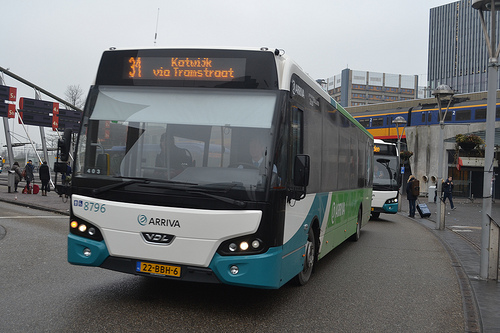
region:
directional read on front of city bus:
[103, 41, 265, 106]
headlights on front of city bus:
[207, 216, 285, 293]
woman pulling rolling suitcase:
[403, 162, 439, 225]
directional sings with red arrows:
[5, 76, 88, 156]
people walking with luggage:
[10, 145, 62, 204]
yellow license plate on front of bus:
[132, 250, 197, 289]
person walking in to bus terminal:
[438, 171, 466, 228]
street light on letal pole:
[433, 66, 466, 186]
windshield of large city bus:
[83, 84, 282, 194]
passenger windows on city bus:
[286, 75, 408, 210]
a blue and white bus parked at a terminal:
[52, 39, 384, 294]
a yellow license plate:
[134, 251, 191, 280]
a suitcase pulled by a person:
[414, 193, 434, 230]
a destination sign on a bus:
[97, 47, 252, 89]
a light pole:
[464, 1, 498, 286]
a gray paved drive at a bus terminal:
[7, 193, 469, 331]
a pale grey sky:
[2, 4, 425, 150]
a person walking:
[438, 171, 458, 209]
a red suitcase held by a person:
[31, 183, 41, 197]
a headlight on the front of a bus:
[236, 238, 250, 255]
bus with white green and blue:
[75, 38, 430, 299]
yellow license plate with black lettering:
[118, 242, 199, 280]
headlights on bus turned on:
[62, 215, 339, 270]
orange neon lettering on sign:
[114, 45, 316, 106]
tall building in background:
[400, 2, 498, 126]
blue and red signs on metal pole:
[5, 61, 93, 141]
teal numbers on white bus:
[40, 185, 127, 219]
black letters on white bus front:
[120, 201, 190, 258]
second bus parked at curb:
[330, 121, 447, 306]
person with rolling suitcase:
[392, 164, 437, 238]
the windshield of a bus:
[72, 91, 287, 203]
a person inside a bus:
[148, 130, 198, 187]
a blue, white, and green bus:
[60, 47, 398, 293]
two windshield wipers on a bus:
[84, 172, 236, 201]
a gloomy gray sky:
[2, 1, 449, 117]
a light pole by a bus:
[389, 115, 410, 217]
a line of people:
[0, 151, 57, 190]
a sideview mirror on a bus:
[284, 146, 321, 204]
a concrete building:
[418, 2, 493, 108]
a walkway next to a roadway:
[394, 184, 498, 330]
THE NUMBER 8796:
[81, 200, 107, 214]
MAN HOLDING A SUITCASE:
[405, 174, 431, 221]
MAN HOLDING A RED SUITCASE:
[18, 159, 39, 196]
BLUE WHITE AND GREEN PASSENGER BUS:
[59, 37, 378, 291]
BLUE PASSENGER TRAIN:
[370, 95, 497, 145]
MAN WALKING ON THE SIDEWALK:
[440, 172, 457, 212]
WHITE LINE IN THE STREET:
[2, 213, 68, 221]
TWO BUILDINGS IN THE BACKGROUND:
[309, 2, 498, 89]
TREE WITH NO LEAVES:
[64, 83, 84, 113]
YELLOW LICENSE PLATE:
[134, 257, 183, 279]